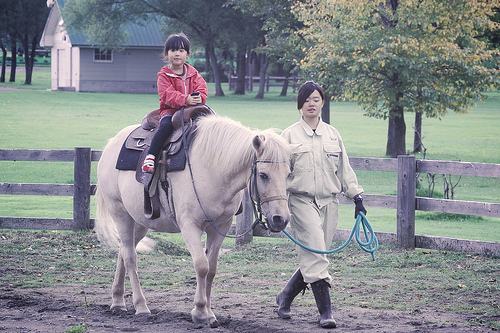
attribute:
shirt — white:
[277, 113, 365, 202]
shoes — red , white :
[136, 151, 166, 169]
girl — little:
[135, 28, 207, 171]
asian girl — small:
[118, 27, 266, 182]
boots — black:
[275, 267, 337, 329]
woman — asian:
[267, 76, 371, 306]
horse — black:
[87, 114, 302, 330]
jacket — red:
[155, 59, 210, 119]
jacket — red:
[152, 60, 209, 107]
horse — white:
[96, 128, 287, 323]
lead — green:
[285, 206, 383, 263]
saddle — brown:
[132, 103, 209, 192]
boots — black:
[262, 267, 342, 332]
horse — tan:
[88, 95, 379, 315]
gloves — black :
[339, 168, 376, 198]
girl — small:
[141, 32, 209, 177]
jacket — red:
[150, 62, 212, 119]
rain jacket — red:
[158, 74, 211, 109]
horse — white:
[92, 117, 291, 320]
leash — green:
[276, 204, 390, 254]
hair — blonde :
[189, 104, 287, 181]